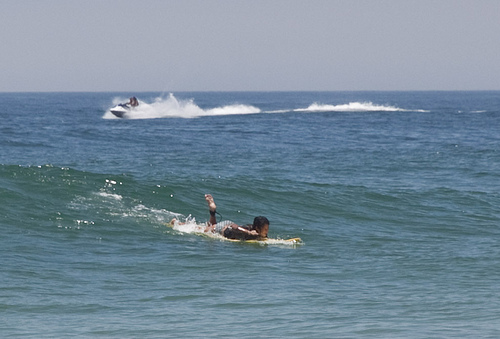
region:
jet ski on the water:
[90, 91, 187, 131]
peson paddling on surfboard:
[164, 185, 302, 265]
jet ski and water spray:
[98, 90, 398, 130]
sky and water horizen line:
[4, 11, 494, 102]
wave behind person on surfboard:
[12, 143, 315, 280]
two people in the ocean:
[93, 88, 309, 338]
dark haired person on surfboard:
[166, 189, 319, 257]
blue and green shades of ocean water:
[6, 97, 109, 329]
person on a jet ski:
[103, 92, 200, 127]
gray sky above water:
[5, 3, 494, 103]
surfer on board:
[184, 188, 276, 259]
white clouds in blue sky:
[22, 29, 80, 69]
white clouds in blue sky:
[118, 9, 159, 47]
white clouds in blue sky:
[61, 15, 108, 53]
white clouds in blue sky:
[217, 25, 255, 56]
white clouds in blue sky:
[305, 33, 349, 65]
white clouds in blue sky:
[431, 9, 485, 53]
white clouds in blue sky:
[258, 28, 298, 63]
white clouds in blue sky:
[138, 19, 188, 59]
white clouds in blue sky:
[307, 43, 361, 80]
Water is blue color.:
[261, 121, 489, 207]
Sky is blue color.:
[15, 15, 468, 74]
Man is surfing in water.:
[182, 182, 284, 252]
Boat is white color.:
[100, 85, 170, 121]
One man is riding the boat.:
[105, 87, 160, 127]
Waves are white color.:
[295, 90, 405, 120]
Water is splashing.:
[97, 87, 202, 122]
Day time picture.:
[15, 16, 477, 306]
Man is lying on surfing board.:
[173, 188, 293, 261]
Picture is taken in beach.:
[23, 23, 485, 320]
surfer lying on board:
[174, 181, 309, 268]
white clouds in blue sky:
[34, 22, 84, 57]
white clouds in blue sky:
[51, 9, 92, 57]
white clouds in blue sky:
[244, 31, 286, 65]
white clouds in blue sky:
[345, 1, 412, 48]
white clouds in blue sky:
[447, 21, 492, 78]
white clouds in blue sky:
[360, 38, 397, 65]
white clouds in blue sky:
[238, 16, 316, 58]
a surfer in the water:
[162, 185, 307, 252]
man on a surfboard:
[162, 185, 304, 252]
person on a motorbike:
[97, 88, 156, 123]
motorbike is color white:
[103, 100, 133, 122]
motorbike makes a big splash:
[96, 85, 210, 125]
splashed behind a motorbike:
[100, 86, 425, 122]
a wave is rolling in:
[6, 146, 488, 221]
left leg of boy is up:
[163, 183, 305, 251]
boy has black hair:
[238, 207, 279, 249]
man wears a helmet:
[119, 88, 144, 115]